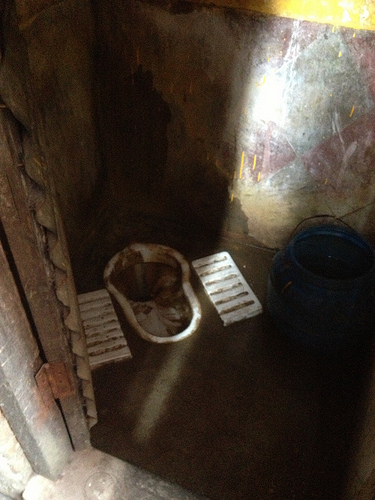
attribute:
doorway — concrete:
[4, 243, 120, 495]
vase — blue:
[247, 214, 356, 335]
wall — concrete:
[86, 5, 373, 250]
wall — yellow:
[165, 11, 352, 247]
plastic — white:
[191, 250, 265, 328]